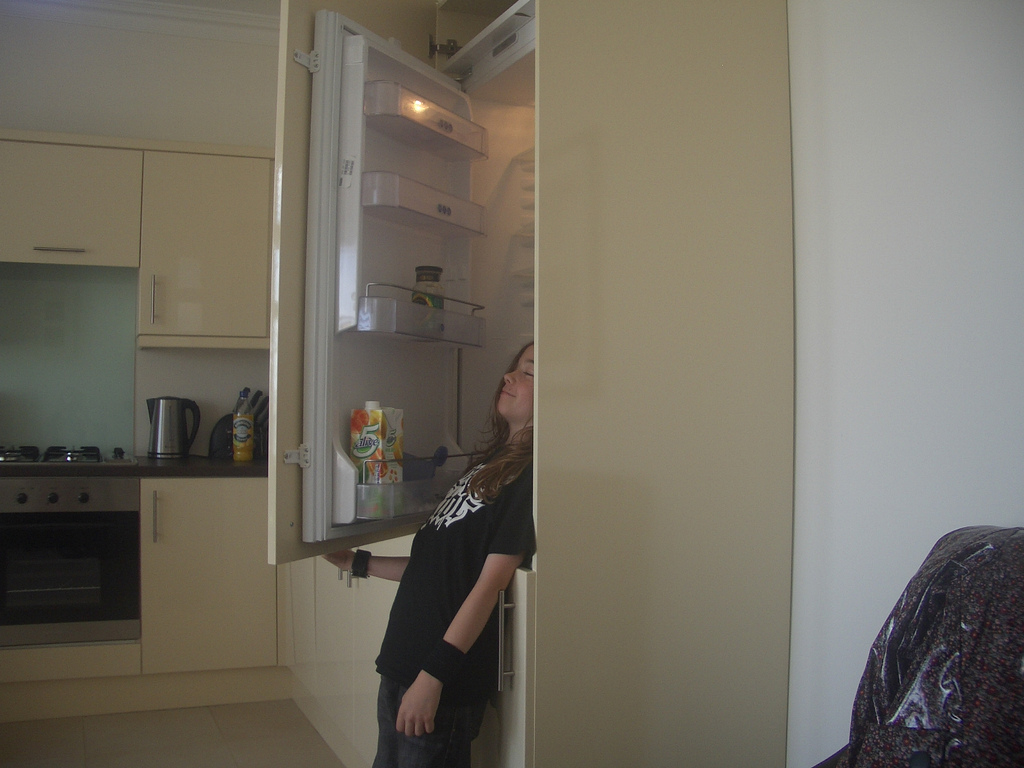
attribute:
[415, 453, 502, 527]
logo — white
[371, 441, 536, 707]
shirt — black